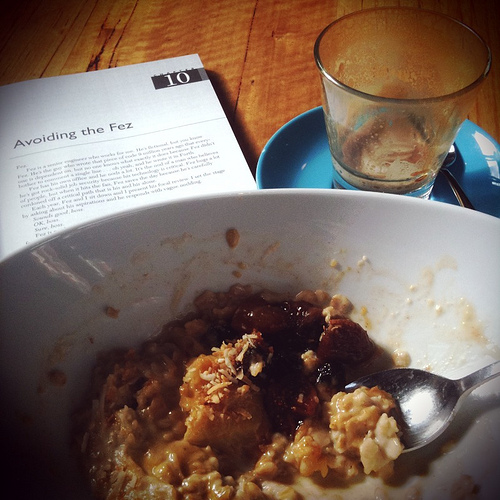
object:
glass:
[314, 7, 492, 202]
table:
[3, 3, 498, 221]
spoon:
[345, 361, 500, 454]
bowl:
[0, 185, 499, 500]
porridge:
[78, 296, 411, 500]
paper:
[1, 54, 255, 262]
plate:
[255, 100, 500, 216]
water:
[331, 129, 445, 192]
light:
[398, 388, 433, 428]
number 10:
[165, 72, 190, 87]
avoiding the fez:
[14, 122, 132, 149]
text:
[16, 128, 220, 238]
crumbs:
[96, 365, 186, 452]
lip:
[313, 6, 491, 104]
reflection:
[473, 131, 500, 186]